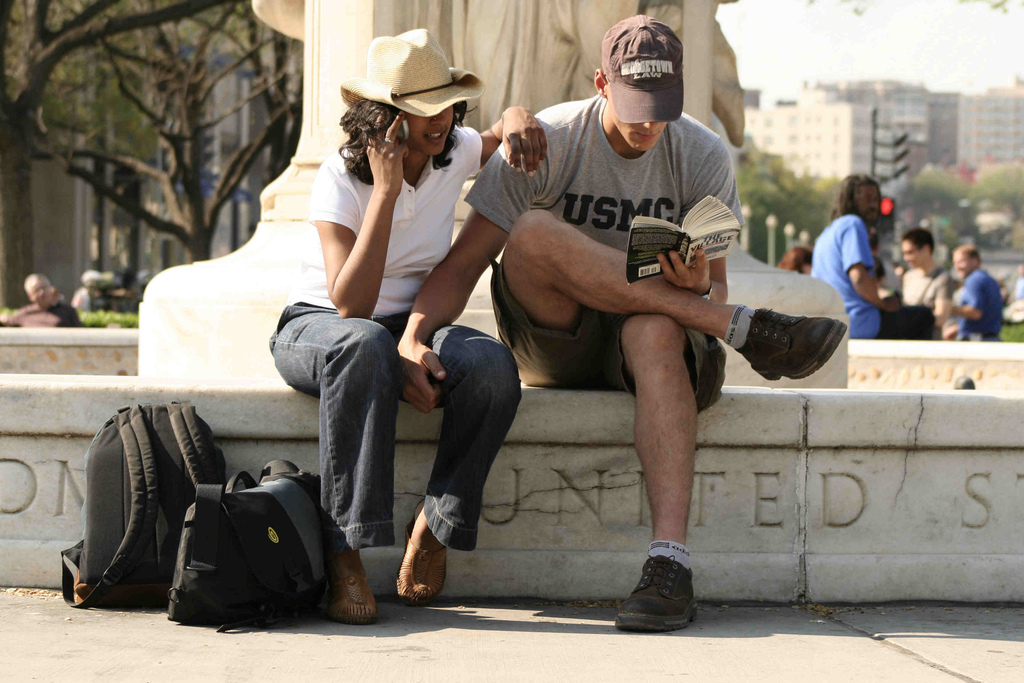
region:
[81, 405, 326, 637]
Black backpacks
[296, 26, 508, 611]
Woman in cowboay hat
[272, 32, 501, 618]
Woman in white tshirt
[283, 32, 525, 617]
Woman wearing blue jeans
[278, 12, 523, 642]
Woman talking on a cell phone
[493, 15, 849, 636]
Man in a brown baseball cap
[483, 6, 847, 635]
Man in a grey tshirt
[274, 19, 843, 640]
Couple sitting down together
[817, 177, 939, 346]
Person in a blue tshirt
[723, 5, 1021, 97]
light in daytime sky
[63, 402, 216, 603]
straps on black backpack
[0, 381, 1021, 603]
words carved into stone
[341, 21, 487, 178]
cowboy hat on head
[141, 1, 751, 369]
bottom of white statue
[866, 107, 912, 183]
side of traffic light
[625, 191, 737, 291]
man is holding a book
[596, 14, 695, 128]
man is wearing a cap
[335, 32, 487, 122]
woman is wearing a hat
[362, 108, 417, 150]
woman is holding a mobile phone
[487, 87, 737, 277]
grey and white shirt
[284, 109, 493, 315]
woman is wearing a white shirt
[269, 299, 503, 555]
woman is wearing jeans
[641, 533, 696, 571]
man is wearing sock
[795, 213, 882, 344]
man is wearing a blue shirt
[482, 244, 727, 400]
man is wearing black shorts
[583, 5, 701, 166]
Hat on a guy's head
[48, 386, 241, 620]
Black bag with a strap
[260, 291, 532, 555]
A pair of blue jeans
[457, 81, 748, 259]
"USMC" written on gray shirt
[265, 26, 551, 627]
a woman talking on a cell phone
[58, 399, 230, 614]
a backpack lying against a wall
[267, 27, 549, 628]
a woman wearing a hat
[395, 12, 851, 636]
a man wearing a hat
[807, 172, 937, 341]
a man sitting down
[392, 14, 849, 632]
a man wearing brown shorts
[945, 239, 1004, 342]
a man wearing a blue shirt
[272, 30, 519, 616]
a person is sitting down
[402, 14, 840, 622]
a person is sitting down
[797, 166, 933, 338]
a person is sitting down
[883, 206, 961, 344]
a person is standing up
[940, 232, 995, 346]
a person is standing up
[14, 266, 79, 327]
a person is sitting down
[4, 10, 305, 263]
a tree in a city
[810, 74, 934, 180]
a building in a city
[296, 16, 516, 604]
a person is sitting down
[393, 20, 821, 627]
a person is sitting down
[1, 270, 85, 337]
a person is sitting down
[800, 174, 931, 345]
a person is sitting down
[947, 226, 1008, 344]
a person is standing up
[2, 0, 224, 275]
a tree in a city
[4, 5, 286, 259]
a tree in a city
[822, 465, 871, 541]
A letter in a wall.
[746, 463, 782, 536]
A letter in a wall.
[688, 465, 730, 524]
A letter in a wall.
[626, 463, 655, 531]
A letter in a wall.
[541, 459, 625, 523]
A letter in a wall.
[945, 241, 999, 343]
A person is standing up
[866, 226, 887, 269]
A person is standing up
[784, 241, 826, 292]
A person is standing up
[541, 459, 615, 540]
A letter on a wall.